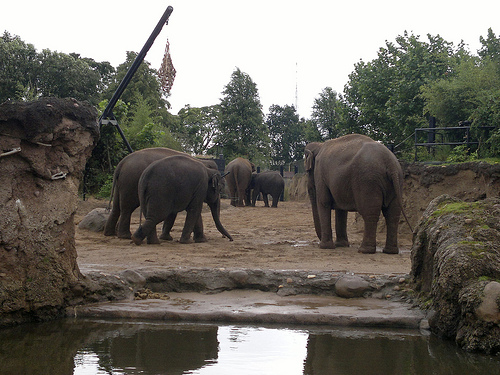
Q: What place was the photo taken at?
A: It was taken at the pen.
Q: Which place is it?
A: It is a pen.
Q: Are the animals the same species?
A: Yes, all the animals are elephants.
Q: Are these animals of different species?
A: No, all the animals are elephants.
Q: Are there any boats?
A: No, there are no boats.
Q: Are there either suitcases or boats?
A: No, there are no boats or suitcases.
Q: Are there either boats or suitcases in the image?
A: No, there are no boats or suitcases.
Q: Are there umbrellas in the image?
A: No, there are no umbrellas.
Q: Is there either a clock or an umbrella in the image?
A: No, there are no umbrellas or clocks.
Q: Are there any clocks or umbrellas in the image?
A: No, there are no umbrellas or clocks.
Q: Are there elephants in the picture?
A: Yes, there is an elephant.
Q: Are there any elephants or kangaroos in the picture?
A: Yes, there is an elephant.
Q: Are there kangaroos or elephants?
A: Yes, there is an elephant.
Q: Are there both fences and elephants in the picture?
A: Yes, there are both an elephant and a fence.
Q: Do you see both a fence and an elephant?
A: Yes, there are both an elephant and a fence.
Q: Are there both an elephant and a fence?
A: Yes, there are both an elephant and a fence.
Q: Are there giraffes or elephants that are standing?
A: Yes, the elephant is standing.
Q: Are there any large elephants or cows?
A: Yes, there is a large elephant.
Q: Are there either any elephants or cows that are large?
A: Yes, the elephant is large.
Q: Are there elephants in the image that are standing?
A: Yes, there is an elephant that is standing.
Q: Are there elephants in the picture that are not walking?
A: Yes, there is an elephant that is standing.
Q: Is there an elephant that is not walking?
A: Yes, there is an elephant that is standing.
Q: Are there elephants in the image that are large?
A: Yes, there is a large elephant.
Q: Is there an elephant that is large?
A: Yes, there is an elephant that is large.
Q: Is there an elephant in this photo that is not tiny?
A: Yes, there is a large elephant.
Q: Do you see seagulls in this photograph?
A: No, there are no seagulls.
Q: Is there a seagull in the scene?
A: No, there are no seagulls.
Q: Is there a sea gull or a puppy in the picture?
A: No, there are no seagulls or puppys.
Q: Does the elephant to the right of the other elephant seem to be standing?
A: Yes, the elephant is standing.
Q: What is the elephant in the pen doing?
A: The elephant is standing.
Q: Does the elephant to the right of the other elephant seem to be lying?
A: No, the elephant is standing.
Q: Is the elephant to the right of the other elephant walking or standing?
A: The elephant is standing.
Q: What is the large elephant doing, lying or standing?
A: The elephant is standing.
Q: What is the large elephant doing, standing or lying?
A: The elephant is standing.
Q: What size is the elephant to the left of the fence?
A: The elephant is large.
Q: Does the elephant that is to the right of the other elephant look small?
A: No, the elephant is large.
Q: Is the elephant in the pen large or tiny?
A: The elephant is large.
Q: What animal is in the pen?
A: The animal is an elephant.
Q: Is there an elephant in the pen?
A: Yes, there is an elephant in the pen.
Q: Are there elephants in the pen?
A: Yes, there is an elephant in the pen.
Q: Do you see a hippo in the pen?
A: No, there is an elephant in the pen.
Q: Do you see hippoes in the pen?
A: No, there is an elephant in the pen.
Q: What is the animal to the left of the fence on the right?
A: The animal is an elephant.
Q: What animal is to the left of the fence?
A: The animal is an elephant.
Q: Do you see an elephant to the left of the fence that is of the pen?
A: Yes, there is an elephant to the left of the fence.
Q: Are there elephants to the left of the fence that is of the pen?
A: Yes, there is an elephant to the left of the fence.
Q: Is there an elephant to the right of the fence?
A: No, the elephant is to the left of the fence.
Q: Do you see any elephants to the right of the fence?
A: No, the elephant is to the left of the fence.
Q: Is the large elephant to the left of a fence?
A: Yes, the elephant is to the left of a fence.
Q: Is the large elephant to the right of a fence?
A: No, the elephant is to the left of a fence.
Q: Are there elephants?
A: Yes, there are elephants.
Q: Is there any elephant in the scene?
A: Yes, there are elephants.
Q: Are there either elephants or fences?
A: Yes, there are elephants.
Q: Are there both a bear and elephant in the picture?
A: No, there are elephants but no bears.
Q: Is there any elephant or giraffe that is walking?
A: Yes, the elephants are walking.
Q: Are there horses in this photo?
A: No, there are no horses.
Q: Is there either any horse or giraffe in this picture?
A: No, there are no horses or giraffes.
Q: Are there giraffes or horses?
A: No, there are no horses or giraffes.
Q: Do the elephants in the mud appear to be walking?
A: Yes, the elephants are walking.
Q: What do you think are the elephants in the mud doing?
A: The elephants are walking.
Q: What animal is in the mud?
A: The elephants are in the mud.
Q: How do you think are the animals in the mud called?
A: The animals are elephants.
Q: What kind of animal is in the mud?
A: The animals are elephants.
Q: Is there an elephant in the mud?
A: Yes, there are elephants in the mud.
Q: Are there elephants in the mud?
A: Yes, there are elephants in the mud.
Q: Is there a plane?
A: No, there are no airplanes.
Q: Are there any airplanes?
A: No, there are no airplanes.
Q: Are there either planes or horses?
A: No, there are no planes or horses.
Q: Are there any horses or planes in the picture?
A: No, there are no planes or horses.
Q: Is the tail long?
A: Yes, the tail is long.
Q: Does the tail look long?
A: Yes, the tail is long.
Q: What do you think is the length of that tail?
A: The tail is long.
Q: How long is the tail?
A: The tail is long.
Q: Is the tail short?
A: No, the tail is long.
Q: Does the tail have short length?
A: No, the tail is long.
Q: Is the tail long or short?
A: The tail is long.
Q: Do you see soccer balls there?
A: No, there are no soccer balls.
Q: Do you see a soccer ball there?
A: No, there are no soccer balls.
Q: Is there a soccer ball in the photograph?
A: No, there are no soccer balls.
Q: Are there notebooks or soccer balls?
A: No, there are no soccer balls or notebooks.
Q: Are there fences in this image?
A: Yes, there is a fence.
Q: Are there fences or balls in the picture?
A: Yes, there is a fence.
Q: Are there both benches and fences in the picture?
A: No, there is a fence but no benches.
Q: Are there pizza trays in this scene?
A: No, there are no pizza trays.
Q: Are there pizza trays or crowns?
A: No, there are no pizza trays or crowns.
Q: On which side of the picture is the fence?
A: The fence is on the right of the image.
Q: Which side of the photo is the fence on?
A: The fence is on the right of the image.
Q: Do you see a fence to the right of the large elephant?
A: Yes, there is a fence to the right of the elephant.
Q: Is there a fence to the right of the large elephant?
A: Yes, there is a fence to the right of the elephant.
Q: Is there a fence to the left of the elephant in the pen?
A: No, the fence is to the right of the elephant.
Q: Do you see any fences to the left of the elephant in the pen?
A: No, the fence is to the right of the elephant.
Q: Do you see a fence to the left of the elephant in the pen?
A: No, the fence is to the right of the elephant.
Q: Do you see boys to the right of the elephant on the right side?
A: No, there is a fence to the right of the elephant.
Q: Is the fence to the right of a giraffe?
A: No, the fence is to the right of the elephant.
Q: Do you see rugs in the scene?
A: No, there are no rugs.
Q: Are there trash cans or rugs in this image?
A: No, there are no rugs or trash cans.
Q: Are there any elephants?
A: Yes, there is an elephant.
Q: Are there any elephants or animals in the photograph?
A: Yes, there is an elephant.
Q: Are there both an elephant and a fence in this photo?
A: Yes, there are both an elephant and a fence.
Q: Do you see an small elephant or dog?
A: Yes, there is a small elephant.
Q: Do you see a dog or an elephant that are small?
A: Yes, the elephant is small.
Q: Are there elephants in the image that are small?
A: Yes, there is a small elephant.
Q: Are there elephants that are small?
A: Yes, there is an elephant that is small.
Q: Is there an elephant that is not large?
A: Yes, there is a small elephant.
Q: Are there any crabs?
A: No, there are no crabs.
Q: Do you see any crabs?
A: No, there are no crabs.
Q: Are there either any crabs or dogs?
A: No, there are no crabs or dogs.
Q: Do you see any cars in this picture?
A: No, there are no cars.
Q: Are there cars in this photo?
A: No, there are no cars.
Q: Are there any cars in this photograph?
A: No, there are no cars.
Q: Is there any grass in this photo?
A: Yes, there is grass.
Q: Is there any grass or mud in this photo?
A: Yes, there is grass.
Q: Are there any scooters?
A: No, there are no scooters.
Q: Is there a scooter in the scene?
A: No, there are no scooters.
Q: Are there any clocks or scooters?
A: No, there are no scooters or clocks.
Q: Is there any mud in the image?
A: Yes, there is mud.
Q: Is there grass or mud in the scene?
A: Yes, there is mud.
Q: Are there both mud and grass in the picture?
A: Yes, there are both mud and grass.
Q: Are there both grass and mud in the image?
A: Yes, there are both mud and grass.